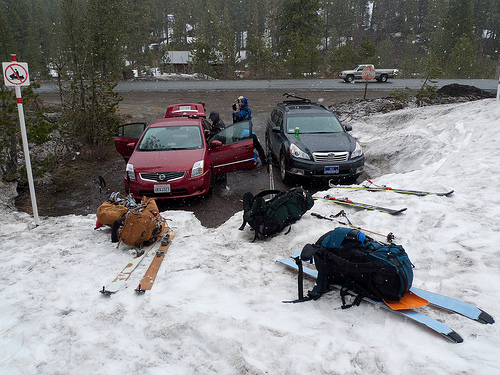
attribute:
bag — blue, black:
[288, 223, 421, 316]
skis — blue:
[273, 219, 498, 343]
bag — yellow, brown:
[97, 188, 165, 246]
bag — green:
[236, 181, 312, 244]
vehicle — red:
[114, 95, 255, 207]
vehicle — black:
[265, 92, 366, 191]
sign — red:
[361, 66, 376, 81]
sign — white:
[1, 61, 31, 88]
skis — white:
[103, 224, 143, 295]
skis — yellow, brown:
[136, 229, 189, 299]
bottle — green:
[289, 122, 301, 141]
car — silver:
[338, 60, 400, 84]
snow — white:
[46, 322, 91, 350]